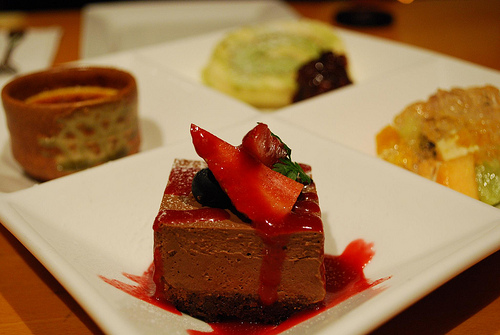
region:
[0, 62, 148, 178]
Round brown bowl on white plate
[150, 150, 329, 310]
Chocolate pastry on white plate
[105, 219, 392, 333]
Red sauce on bottom of chocolate pastry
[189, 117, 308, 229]
Red strawberry slice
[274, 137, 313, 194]
Green leaf on chocolate pastry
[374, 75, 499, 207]
Fruit pastry on white plate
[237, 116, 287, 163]
Strawberry slice on top of strawberry slice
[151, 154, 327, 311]
Chocolate pastry is square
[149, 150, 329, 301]
Red sauce drizzled on chocolate pastry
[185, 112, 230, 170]
Red sauce drizzled on strawberry slice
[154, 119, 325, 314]
a piece of chocolate mousse cake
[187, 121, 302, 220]
a strawberry wedge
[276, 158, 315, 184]
a sprig of mint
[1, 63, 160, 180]
a small creme brulee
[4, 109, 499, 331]
a square dessert plate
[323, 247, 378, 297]
strawberry sauce smeared on a plate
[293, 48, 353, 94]
a fruity jam like sauce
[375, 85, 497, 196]
a fruit dessert with peaches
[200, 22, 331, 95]
a pastry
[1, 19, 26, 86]
a dessert fork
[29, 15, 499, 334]
four desserts on a plate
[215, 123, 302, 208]
two slices of strawberry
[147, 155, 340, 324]
a chocolate mouse cake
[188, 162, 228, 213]
a blueberry on a cake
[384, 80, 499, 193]
a fruit pie with kiwi and peaches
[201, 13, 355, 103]
a key lime pie with blackberry jam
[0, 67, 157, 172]
creme brulee in a pot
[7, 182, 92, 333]
a white plate on a wooden table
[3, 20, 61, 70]
a utensil on a paper napkin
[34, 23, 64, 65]
a white paper napkin on a wooden table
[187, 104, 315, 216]
fruit on a cake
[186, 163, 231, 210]
a small blueberry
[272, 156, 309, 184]
the green stem of the strawberry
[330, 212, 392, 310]
syrup on the plate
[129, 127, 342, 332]
a piece of chocolate cake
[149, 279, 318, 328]
the cake crust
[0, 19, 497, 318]
desert on the paltes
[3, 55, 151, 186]
a bowl on the plate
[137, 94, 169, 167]
shadows on the palte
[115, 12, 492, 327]
desert on the table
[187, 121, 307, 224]
Strawberry on top of chocolate cake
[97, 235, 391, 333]
Red sauce below chocolate cake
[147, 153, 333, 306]
Chocolate cake is brown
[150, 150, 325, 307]
Chocolate cake on white plate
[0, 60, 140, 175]
Round small bowl on white plate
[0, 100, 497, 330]
Plate is square and white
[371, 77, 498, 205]
Fruit pastry on white square plate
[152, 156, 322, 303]
Red sauce drizzled on chocolate cake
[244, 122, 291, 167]
Strawberry slice on top of another strawberry slice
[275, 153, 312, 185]
Green leaf on strawberry slice